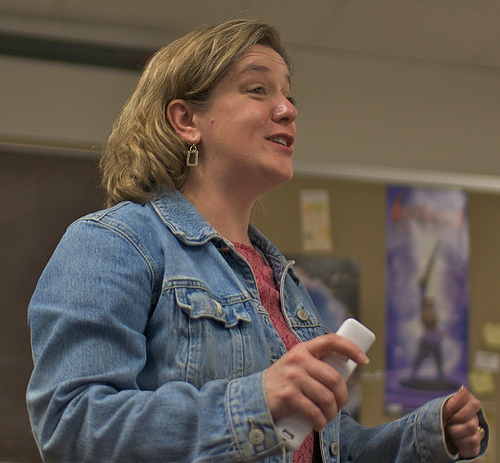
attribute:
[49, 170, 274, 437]
jacket — jean, blue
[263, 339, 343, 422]
hand — fist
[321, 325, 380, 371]
remote — white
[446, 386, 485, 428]
finger — curved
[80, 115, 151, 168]
hair — blonde, tucked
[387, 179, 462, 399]
poster — blue, purple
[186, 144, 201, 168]
earring — gold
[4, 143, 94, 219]
doorway — dark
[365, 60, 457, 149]
wall — white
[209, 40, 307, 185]
face — smiling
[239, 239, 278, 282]
shirt — red